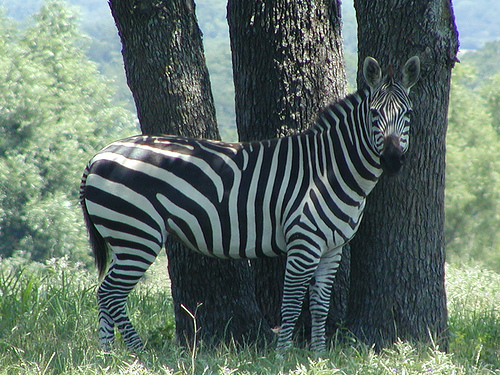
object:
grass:
[0, 256, 499, 374]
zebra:
[79, 56, 421, 359]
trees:
[104, 0, 278, 354]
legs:
[276, 229, 324, 358]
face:
[368, 80, 413, 177]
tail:
[78, 160, 108, 282]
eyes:
[369, 108, 379, 116]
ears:
[362, 55, 384, 88]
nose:
[378, 135, 405, 177]